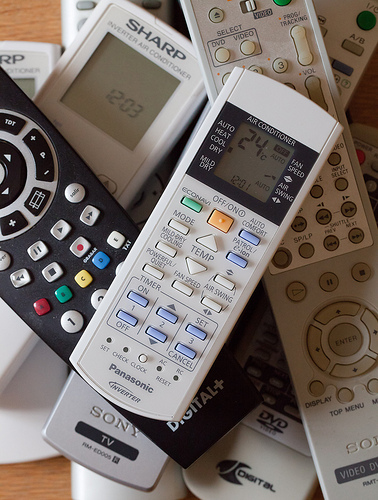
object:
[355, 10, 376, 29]
button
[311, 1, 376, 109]
remote control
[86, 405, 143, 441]
logo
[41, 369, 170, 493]
remote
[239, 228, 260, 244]
button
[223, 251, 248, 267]
button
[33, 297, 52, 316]
button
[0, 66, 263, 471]
remot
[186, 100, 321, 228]
display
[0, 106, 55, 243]
buttons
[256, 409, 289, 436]
logo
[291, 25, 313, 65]
button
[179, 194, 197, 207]
button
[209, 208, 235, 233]
button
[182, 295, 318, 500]
remote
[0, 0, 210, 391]
remote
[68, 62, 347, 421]
remote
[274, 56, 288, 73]
buttons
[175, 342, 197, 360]
button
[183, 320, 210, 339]
button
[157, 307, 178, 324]
button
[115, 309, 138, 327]
button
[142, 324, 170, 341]
button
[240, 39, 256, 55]
button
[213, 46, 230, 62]
button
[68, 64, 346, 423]
iron work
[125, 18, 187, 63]
logo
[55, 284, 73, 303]
green button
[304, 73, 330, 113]
volume button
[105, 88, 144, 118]
12:03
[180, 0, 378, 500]
remote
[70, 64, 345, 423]
box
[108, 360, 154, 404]
logo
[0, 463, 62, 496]
table